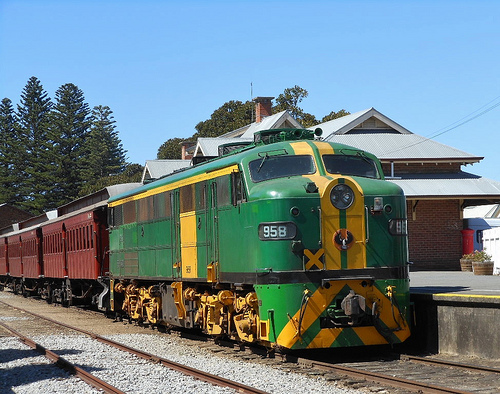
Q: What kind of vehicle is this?
A: Train.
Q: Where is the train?
A: Train track.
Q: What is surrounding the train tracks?
A: Gravel.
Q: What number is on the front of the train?
A: 958.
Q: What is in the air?
A: Power lines.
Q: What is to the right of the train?
A: Houses.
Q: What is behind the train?
A: Trees.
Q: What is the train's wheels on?
A: A metal track.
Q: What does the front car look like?
A: Green and yellow.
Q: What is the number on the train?
A: 958.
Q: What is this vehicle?
A: A train.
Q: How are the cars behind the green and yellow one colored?
A: Reddish brown.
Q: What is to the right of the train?
A: A building.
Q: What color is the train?
A: Green.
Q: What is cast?
A: Shadow.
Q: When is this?
A: Daytime.